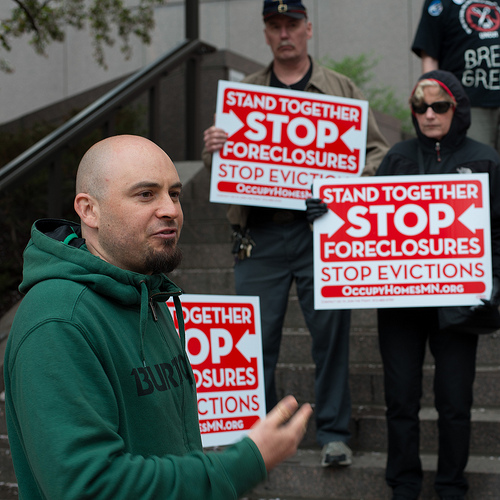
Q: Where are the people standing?
A: Steps.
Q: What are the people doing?
A: Protesting.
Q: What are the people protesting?
A: Foreclosures and evictions.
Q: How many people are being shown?
A: Four.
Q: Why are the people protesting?
A: Beliefs.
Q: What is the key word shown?
A: Stop.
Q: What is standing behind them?
A: Building.